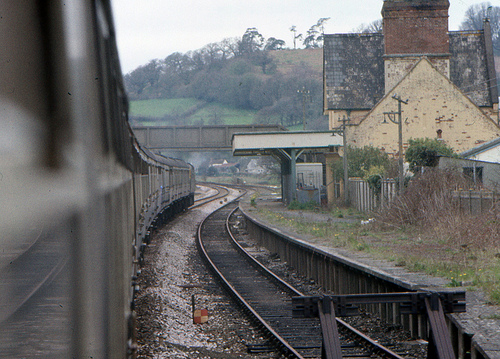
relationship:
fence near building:
[412, 179, 498, 219] [313, 10, 498, 202]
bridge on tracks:
[138, 119, 295, 155] [198, 174, 454, 357]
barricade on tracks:
[291, 289, 470, 357] [193, 182, 400, 356]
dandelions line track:
[249, 198, 327, 229] [164, 173, 421, 355]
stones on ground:
[123, 171, 450, 355] [121, 95, 498, 357]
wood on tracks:
[212, 263, 257, 273] [202, 225, 301, 308]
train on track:
[2, 0, 195, 359] [198, 174, 413, 348]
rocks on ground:
[132, 243, 208, 340] [133, 83, 468, 300]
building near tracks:
[332, 14, 467, 190] [149, 145, 349, 339]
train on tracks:
[2, 7, 192, 354] [194, 176, 229, 203]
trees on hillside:
[196, 16, 363, 131] [148, 12, 388, 180]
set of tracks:
[61, 98, 385, 349] [176, 112, 408, 340]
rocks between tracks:
[132, 243, 208, 340] [195, 199, 409, 357]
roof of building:
[319, 31, 384, 112] [322, 28, 492, 213]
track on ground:
[195, 180, 402, 354] [132, 189, 499, 351]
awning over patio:
[230, 131, 345, 155] [235, 131, 340, 203]